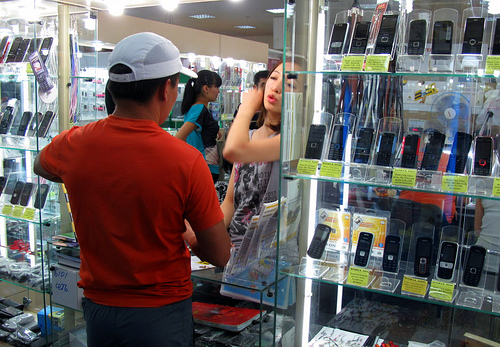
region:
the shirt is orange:
[35, 99, 225, 321]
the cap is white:
[103, 9, 216, 138]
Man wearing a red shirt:
[39, 29, 236, 345]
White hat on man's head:
[104, 30, 204, 86]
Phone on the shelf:
[304, 219, 333, 266]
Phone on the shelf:
[345, 220, 377, 276]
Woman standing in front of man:
[215, 55, 297, 252]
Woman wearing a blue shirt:
[172, 58, 226, 157]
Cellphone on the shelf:
[295, 119, 324, 166]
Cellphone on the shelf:
[320, 13, 350, 60]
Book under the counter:
[172, 284, 269, 339]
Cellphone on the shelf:
[457, 13, 488, 57]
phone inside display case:
[393, 129, 426, 174]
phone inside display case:
[351, 115, 371, 173]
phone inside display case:
[370, 1, 397, 65]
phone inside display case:
[299, 115, 334, 170]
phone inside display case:
[407, 228, 442, 286]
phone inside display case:
[377, 227, 404, 283]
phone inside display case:
[350, 227, 378, 275]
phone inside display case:
[296, 211, 339, 266]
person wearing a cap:
[98, 26, 208, 91]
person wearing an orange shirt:
[25, 107, 239, 337]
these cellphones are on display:
[312, 4, 499, 337]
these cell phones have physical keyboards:
[298, 5, 498, 315]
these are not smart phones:
[296, 14, 499, 340]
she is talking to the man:
[197, 27, 324, 302]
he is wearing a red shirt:
[20, 5, 240, 321]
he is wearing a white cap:
[88, 30, 211, 95]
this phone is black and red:
[395, 125, 420, 175]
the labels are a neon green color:
[340, 50, 397, 70]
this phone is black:
[300, 212, 335, 262]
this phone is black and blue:
[375, 127, 397, 167]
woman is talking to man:
[36, 15, 293, 343]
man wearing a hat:
[104, 28, 199, 95]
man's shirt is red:
[41, 110, 223, 307]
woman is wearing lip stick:
[258, 88, 279, 109]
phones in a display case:
[293, 3, 498, 301]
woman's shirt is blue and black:
[180, 89, 225, 161]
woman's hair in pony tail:
[175, 68, 227, 115]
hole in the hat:
[100, 55, 131, 78]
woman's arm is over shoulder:
[220, 81, 293, 163]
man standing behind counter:
[26, 23, 242, 343]